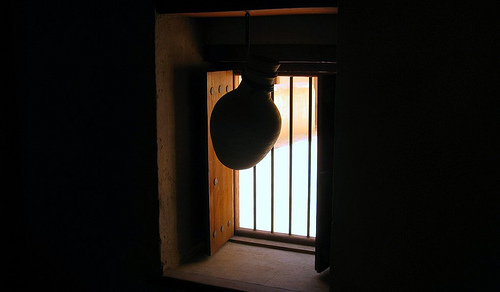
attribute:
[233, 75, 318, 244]
bars — brown, skinny, metal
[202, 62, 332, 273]
door — brown, rounded, wooden, smooth, metal, black, riveted, small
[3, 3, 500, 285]
wall — dark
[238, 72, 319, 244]
window — lit, square, brown, wooden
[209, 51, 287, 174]
object — hanging, brown, white, round